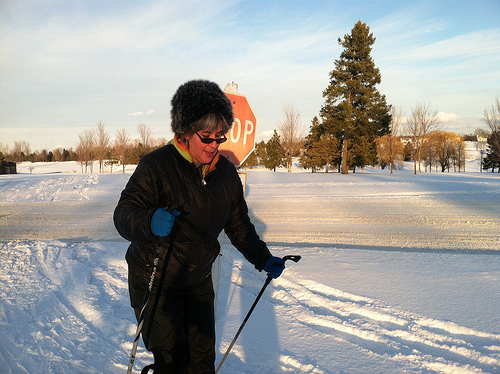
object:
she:
[112, 79, 285, 374]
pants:
[126, 257, 218, 373]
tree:
[403, 104, 445, 174]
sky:
[7, 6, 479, 143]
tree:
[299, 21, 396, 170]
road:
[2, 199, 499, 246]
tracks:
[3, 241, 144, 371]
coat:
[112, 144, 271, 292]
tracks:
[222, 257, 499, 373]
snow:
[216, 177, 498, 372]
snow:
[0, 163, 135, 369]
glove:
[151, 206, 181, 236]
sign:
[222, 94, 256, 167]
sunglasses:
[195, 133, 228, 144]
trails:
[3, 240, 499, 370]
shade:
[203, 219, 278, 372]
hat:
[171, 79, 236, 135]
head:
[174, 79, 232, 163]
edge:
[297, 256, 302, 262]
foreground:
[5, 128, 495, 176]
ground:
[5, 168, 495, 372]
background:
[0, 0, 499, 179]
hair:
[180, 115, 230, 138]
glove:
[263, 256, 285, 279]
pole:
[215, 255, 302, 372]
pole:
[126, 236, 172, 373]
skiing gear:
[113, 137, 301, 374]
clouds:
[11, 4, 485, 136]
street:
[6, 182, 488, 252]